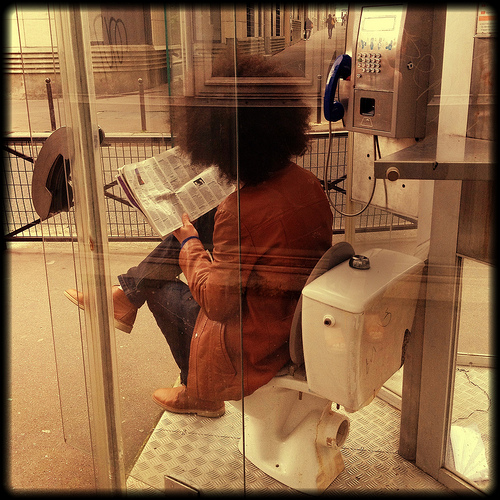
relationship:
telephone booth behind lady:
[71, 13, 498, 499] [57, 44, 318, 421]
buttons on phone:
[355, 43, 385, 83] [311, 3, 428, 134]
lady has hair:
[57, 44, 318, 421] [166, 53, 305, 180]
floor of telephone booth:
[136, 383, 439, 488] [71, 13, 498, 499]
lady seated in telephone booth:
[57, 44, 318, 421] [71, 13, 498, 499]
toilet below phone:
[209, 244, 412, 495] [311, 3, 428, 134]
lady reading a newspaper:
[57, 44, 318, 421] [112, 151, 242, 236]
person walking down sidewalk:
[319, 13, 340, 36] [249, 10, 344, 129]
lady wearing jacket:
[57, 44, 318, 421] [170, 176, 325, 405]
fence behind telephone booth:
[12, 129, 421, 246] [71, 13, 498, 499]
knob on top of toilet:
[349, 249, 372, 272] [209, 244, 412, 495]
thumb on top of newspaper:
[179, 212, 193, 222] [112, 151, 242, 236]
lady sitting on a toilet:
[57, 44, 318, 421] [209, 244, 412, 495]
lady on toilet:
[57, 44, 318, 421] [209, 244, 412, 495]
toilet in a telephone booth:
[209, 244, 412, 495] [71, 13, 498, 499]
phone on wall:
[311, 3, 428, 134] [413, 11, 475, 479]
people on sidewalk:
[301, 16, 339, 39] [249, 10, 344, 129]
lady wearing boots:
[57, 44, 318, 421] [66, 281, 226, 422]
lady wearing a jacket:
[57, 44, 318, 421] [170, 176, 325, 405]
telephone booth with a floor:
[71, 13, 498, 499] [136, 383, 439, 488]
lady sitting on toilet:
[57, 44, 318, 421] [209, 244, 412, 495]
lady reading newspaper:
[57, 44, 318, 421] [112, 151, 242, 236]